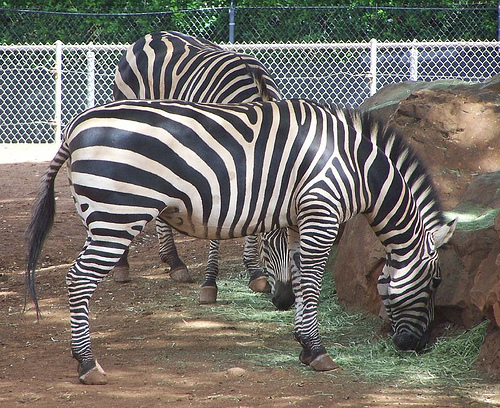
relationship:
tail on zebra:
[24, 135, 69, 325] [25, 95, 459, 385]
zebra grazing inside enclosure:
[25, 95, 459, 385] [4, 5, 483, 394]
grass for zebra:
[166, 246, 498, 393] [25, 95, 459, 385]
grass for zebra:
[166, 246, 498, 393] [110, 27, 347, 308]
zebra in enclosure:
[25, 95, 459, 385] [0, 41, 136, 167]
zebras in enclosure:
[107, 26, 299, 311] [211, 39, 498, 112]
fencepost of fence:
[225, 4, 239, 39] [2, 2, 499, 140]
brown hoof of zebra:
[189, 274, 222, 311] [100, 21, 285, 121]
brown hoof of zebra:
[241, 264, 276, 301] [100, 21, 285, 121]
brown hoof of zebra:
[110, 259, 135, 289] [100, 21, 285, 121]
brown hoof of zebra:
[165, 256, 197, 288] [100, 21, 285, 121]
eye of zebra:
[432, 275, 443, 288] [25, 95, 459, 385]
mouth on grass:
[387, 328, 417, 353] [351, 311, 462, 396]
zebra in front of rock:
[25, 95, 459, 385] [284, 57, 497, 375]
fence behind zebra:
[5, 39, 499, 134] [100, 24, 294, 307]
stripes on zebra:
[18, 102, 462, 383] [25, 95, 459, 385]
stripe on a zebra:
[66, 124, 216, 235] [25, 95, 459, 385]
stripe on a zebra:
[71, 154, 196, 216] [25, 95, 459, 385]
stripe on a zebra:
[86, 222, 142, 240] [25, 95, 459, 385]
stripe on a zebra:
[267, 97, 316, 231] [25, 95, 459, 385]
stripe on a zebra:
[355, 115, 378, 209] [25, 95, 459, 385]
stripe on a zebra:
[357, 132, 374, 209] [25, 95, 459, 385]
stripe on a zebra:
[82, 254, 117, 268] [25, 95, 459, 385]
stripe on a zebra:
[391, 275, 422, 286] [25, 95, 459, 385]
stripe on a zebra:
[321, 112, 338, 162] [25, 95, 459, 385]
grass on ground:
[166, 246, 498, 393] [151, 272, 270, 398]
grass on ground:
[166, 246, 498, 393] [116, 305, 291, 398]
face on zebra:
[382, 255, 456, 352] [25, 95, 459, 385]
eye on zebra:
[431, 272, 443, 292] [25, 95, 459, 385]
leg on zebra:
[297, 187, 341, 340] [25, 95, 459, 385]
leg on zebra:
[67, 211, 138, 358] [25, 95, 459, 385]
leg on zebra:
[240, 226, 266, 273] [100, 24, 294, 307]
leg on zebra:
[203, 231, 223, 286] [100, 24, 294, 307]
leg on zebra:
[158, 211, 185, 267] [100, 24, 294, 307]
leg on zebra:
[62, 211, 138, 383] [25, 95, 459, 385]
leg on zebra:
[62, 211, 138, 383] [100, 24, 294, 307]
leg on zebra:
[240, 226, 263, 296] [100, 24, 294, 307]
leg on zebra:
[197, 231, 224, 309] [100, 24, 294, 307]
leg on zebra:
[158, 211, 196, 280] [100, 24, 294, 307]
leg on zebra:
[67, 211, 138, 358] [103, 20, 280, 286]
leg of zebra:
[290, 213, 338, 375] [27, 79, 496, 367]